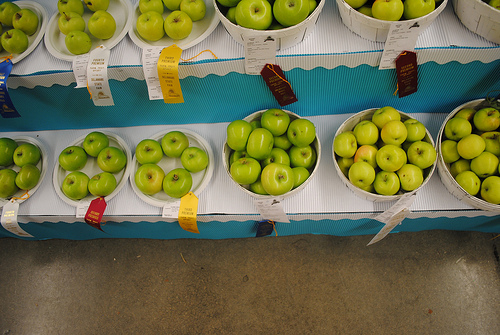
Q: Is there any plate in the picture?
A: Yes, there is a plate.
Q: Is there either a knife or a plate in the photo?
A: Yes, there is a plate.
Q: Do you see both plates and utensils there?
A: No, there is a plate but no utensils.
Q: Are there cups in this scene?
A: No, there are no cups.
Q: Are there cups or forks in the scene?
A: No, there are no cups or forks.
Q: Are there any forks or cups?
A: No, there are no cups or forks.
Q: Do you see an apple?
A: Yes, there are apples.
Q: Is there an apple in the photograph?
A: Yes, there are apples.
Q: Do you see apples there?
A: Yes, there are apples.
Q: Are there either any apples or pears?
A: Yes, there are apples.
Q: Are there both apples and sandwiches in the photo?
A: No, there are apples but no sandwiches.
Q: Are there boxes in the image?
A: No, there are no boxes.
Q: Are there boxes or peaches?
A: No, there are no boxes or peaches.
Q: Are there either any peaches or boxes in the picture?
A: No, there are no boxes or peaches.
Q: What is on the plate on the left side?
A: The apples are on the plate.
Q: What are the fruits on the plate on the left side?
A: The fruits are apples.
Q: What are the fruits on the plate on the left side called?
A: The fruits are apples.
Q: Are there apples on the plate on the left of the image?
A: Yes, there are apples on the plate.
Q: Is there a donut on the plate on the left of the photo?
A: No, there are apples on the plate.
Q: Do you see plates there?
A: Yes, there is a plate.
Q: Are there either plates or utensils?
A: Yes, there is a plate.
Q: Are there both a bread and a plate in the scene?
A: No, there is a plate but no breads.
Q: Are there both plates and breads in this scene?
A: No, there is a plate but no breads.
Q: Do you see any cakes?
A: No, there are no cakes.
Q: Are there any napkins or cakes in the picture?
A: No, there are no cakes or napkins.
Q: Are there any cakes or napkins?
A: No, there are no cakes or napkins.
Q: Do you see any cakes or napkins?
A: No, there are no cakes or napkins.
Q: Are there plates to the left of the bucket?
A: Yes, there is a plate to the left of the bucket.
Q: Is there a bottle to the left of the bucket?
A: No, there is a plate to the left of the bucket.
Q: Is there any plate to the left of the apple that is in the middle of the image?
A: Yes, there is a plate to the left of the apple.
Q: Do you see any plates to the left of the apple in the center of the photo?
A: Yes, there is a plate to the left of the apple.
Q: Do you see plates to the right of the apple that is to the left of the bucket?
A: No, the plate is to the left of the apple.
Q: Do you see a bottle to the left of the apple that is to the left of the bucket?
A: No, there is a plate to the left of the apple.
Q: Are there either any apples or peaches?
A: Yes, there are apples.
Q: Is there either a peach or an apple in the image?
A: Yes, there are apples.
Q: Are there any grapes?
A: No, there are no grapes.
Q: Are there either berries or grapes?
A: No, there are no grapes or berries.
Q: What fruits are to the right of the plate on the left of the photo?
A: The fruits are apples.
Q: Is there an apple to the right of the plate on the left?
A: Yes, there are apples to the right of the plate.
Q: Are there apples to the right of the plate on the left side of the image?
A: Yes, there are apples to the right of the plate.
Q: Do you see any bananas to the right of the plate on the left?
A: No, there are apples to the right of the plate.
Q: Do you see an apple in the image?
A: Yes, there is an apple.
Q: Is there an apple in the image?
A: Yes, there is an apple.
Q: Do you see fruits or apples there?
A: Yes, there is an apple.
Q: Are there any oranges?
A: No, there are no oranges.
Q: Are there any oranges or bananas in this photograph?
A: No, there are no oranges or bananas.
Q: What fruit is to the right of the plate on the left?
A: The fruit is an apple.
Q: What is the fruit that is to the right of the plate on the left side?
A: The fruit is an apple.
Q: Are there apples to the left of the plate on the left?
A: No, the apple is to the right of the plate.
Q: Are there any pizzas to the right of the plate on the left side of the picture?
A: No, there is an apple to the right of the plate.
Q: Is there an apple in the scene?
A: Yes, there is an apple.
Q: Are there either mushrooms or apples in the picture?
A: Yes, there is an apple.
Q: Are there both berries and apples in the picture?
A: No, there is an apple but no berries.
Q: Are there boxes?
A: No, there are no boxes.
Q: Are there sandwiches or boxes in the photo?
A: No, there are no boxes or sandwiches.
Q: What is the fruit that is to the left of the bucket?
A: The fruit is an apple.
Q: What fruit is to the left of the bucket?
A: The fruit is an apple.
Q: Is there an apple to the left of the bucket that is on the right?
A: Yes, there is an apple to the left of the bucket.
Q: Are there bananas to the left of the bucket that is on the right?
A: No, there is an apple to the left of the bucket.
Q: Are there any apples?
A: Yes, there is an apple.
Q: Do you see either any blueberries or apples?
A: Yes, there is an apple.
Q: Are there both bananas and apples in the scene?
A: No, there is an apple but no bananas.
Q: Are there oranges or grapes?
A: No, there are no grapes or oranges.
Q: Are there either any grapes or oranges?
A: No, there are no grapes or oranges.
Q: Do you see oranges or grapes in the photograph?
A: No, there are no grapes or oranges.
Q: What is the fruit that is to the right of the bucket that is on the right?
A: The fruit is an apple.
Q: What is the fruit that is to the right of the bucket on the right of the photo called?
A: The fruit is an apple.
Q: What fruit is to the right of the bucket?
A: The fruit is an apple.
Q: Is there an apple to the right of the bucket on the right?
A: Yes, there is an apple to the right of the bucket.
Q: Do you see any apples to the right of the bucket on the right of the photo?
A: Yes, there is an apple to the right of the bucket.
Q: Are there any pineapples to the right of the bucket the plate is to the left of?
A: No, there is an apple to the right of the bucket.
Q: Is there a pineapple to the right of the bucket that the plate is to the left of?
A: No, there is an apple to the right of the bucket.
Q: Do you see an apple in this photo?
A: Yes, there is an apple.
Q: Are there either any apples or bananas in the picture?
A: Yes, there is an apple.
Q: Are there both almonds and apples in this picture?
A: No, there is an apple but no almonds.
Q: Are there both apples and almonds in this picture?
A: No, there is an apple but no almonds.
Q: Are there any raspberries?
A: No, there are no raspberries.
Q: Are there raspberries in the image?
A: No, there are no raspberries.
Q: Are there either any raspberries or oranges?
A: No, there are no raspberries or oranges.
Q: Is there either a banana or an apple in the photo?
A: Yes, there is an apple.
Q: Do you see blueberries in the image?
A: No, there are no blueberries.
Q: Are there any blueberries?
A: No, there are no blueberries.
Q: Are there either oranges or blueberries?
A: No, there are no blueberries or oranges.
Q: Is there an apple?
A: Yes, there is an apple.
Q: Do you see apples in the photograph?
A: Yes, there is an apple.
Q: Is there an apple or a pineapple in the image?
A: Yes, there is an apple.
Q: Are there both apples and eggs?
A: No, there is an apple but no eggs.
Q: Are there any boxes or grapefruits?
A: No, there are no boxes or grapefruits.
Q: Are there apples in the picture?
A: Yes, there is an apple.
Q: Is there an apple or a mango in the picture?
A: Yes, there is an apple.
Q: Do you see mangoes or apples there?
A: Yes, there is an apple.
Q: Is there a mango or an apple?
A: Yes, there is an apple.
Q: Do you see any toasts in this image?
A: No, there are no toasts.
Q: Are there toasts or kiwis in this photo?
A: No, there are no toasts or kiwis.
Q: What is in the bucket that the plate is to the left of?
A: The apple is in the bucket.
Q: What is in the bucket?
A: The apple is in the bucket.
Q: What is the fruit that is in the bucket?
A: The fruit is an apple.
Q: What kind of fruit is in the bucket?
A: The fruit is an apple.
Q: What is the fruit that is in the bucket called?
A: The fruit is an apple.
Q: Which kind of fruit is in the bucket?
A: The fruit is an apple.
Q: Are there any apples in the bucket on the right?
A: Yes, there is an apple in the bucket.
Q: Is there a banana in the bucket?
A: No, there is an apple in the bucket.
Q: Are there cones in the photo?
A: No, there are no cones.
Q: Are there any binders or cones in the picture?
A: No, there are no cones or binders.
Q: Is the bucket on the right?
A: Yes, the bucket is on the right of the image.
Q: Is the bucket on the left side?
A: No, the bucket is on the right of the image.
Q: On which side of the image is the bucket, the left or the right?
A: The bucket is on the right of the image.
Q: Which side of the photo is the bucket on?
A: The bucket is on the right of the image.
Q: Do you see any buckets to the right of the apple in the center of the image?
A: Yes, there is a bucket to the right of the apple.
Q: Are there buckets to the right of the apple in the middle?
A: Yes, there is a bucket to the right of the apple.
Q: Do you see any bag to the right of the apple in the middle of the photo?
A: No, there is a bucket to the right of the apple.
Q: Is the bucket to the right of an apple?
A: Yes, the bucket is to the right of an apple.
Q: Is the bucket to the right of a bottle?
A: No, the bucket is to the right of an apple.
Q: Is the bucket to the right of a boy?
A: No, the bucket is to the right of the plate.